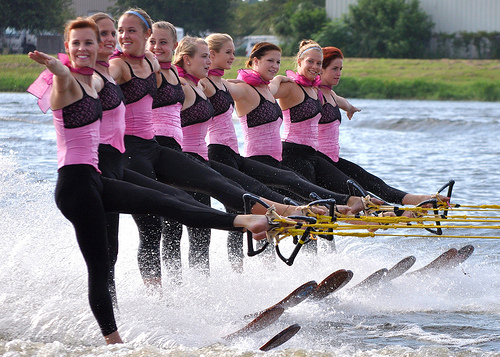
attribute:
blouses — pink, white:
[41, 92, 328, 189]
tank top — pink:
[38, 72, 101, 167]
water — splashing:
[3, 228, 73, 354]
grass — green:
[428, 60, 473, 86]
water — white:
[415, 107, 477, 162]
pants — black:
[54, 163, 235, 330]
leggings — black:
[52, 161, 240, 335]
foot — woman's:
[248, 207, 277, 232]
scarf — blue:
[115, 4, 153, 30]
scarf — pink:
[22, 52, 94, 96]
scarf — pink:
[106, 49, 144, 62]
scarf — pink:
[235, 65, 272, 88]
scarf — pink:
[281, 65, 321, 85]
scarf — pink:
[172, 64, 199, 84]